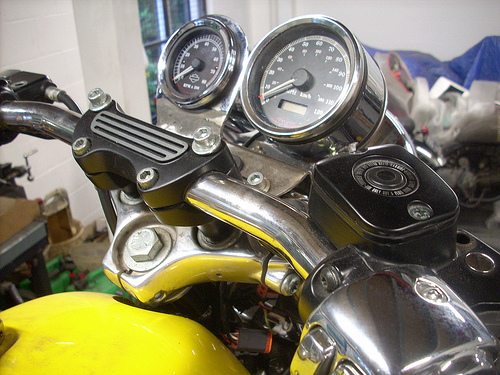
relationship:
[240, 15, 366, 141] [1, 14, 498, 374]
speedometer on motorcycle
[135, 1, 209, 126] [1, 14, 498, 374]
window behind motorcycle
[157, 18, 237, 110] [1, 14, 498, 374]
tachometer on motorcycle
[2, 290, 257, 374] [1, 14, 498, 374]
petrol tank on motorcycle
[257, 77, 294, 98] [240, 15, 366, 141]
needle on speedometer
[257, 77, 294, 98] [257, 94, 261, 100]
needle with tip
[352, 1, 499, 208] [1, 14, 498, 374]
area in front of motorcycle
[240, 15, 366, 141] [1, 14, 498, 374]
speedometer for motorcycle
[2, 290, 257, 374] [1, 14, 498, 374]
petrol tank for motorcycle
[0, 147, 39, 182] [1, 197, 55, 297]
vice grip on work bench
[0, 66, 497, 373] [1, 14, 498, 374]
handles of motorcycle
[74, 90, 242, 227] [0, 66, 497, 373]
clamp holding handles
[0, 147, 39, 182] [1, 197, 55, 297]
vice grip secured to work bench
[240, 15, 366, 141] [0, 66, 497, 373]
speedometer attached to handles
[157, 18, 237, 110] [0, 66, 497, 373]
tachometer on left of handles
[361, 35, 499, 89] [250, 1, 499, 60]
tarp against rear wall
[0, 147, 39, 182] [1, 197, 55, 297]
vice grip attached to work bench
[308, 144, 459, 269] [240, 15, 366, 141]
box next to speedometer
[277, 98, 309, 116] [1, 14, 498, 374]
odometer on motorcycle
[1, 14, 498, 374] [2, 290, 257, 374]
motorcycle with petrol tank